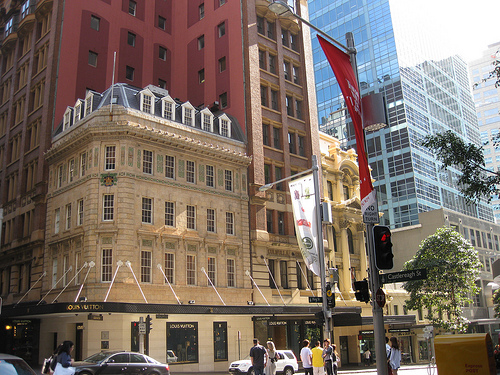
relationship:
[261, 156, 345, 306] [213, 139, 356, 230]
banner on pole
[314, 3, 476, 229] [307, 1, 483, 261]
glass covering building